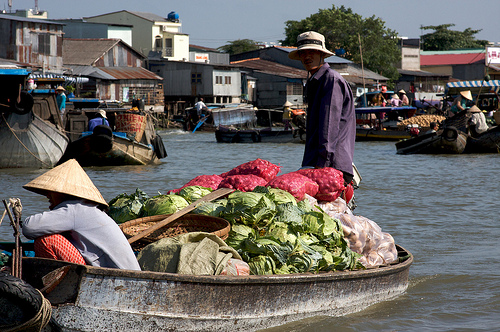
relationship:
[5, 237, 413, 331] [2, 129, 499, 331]
boat in water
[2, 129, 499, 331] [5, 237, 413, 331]
water for boat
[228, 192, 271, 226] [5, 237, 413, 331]
cabbage in boat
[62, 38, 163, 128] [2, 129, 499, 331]
building behind water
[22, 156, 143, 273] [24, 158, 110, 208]
woman wearing hat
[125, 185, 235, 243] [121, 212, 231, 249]
oar on basket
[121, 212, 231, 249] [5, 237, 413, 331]
basket in boat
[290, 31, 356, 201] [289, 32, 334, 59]
man wearing hat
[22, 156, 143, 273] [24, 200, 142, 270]
woman wearing shirt